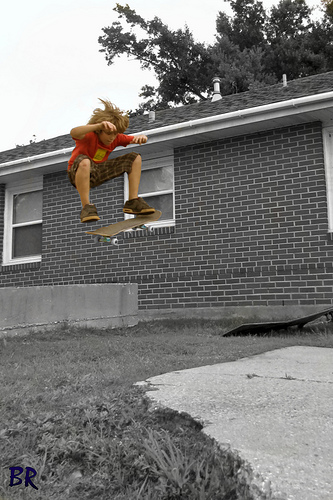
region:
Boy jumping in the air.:
[58, 92, 229, 251]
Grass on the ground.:
[90, 411, 282, 487]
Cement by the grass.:
[99, 328, 329, 477]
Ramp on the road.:
[226, 288, 329, 385]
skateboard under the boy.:
[87, 221, 181, 262]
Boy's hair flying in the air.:
[86, 96, 139, 134]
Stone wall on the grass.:
[27, 264, 158, 335]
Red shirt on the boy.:
[52, 115, 158, 166]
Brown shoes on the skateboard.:
[75, 203, 169, 234]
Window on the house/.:
[5, 182, 87, 282]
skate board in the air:
[80, 206, 174, 239]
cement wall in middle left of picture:
[1, 280, 139, 333]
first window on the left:
[2, 172, 45, 267]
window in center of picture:
[121, 148, 177, 234]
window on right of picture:
[316, 119, 332, 237]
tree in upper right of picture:
[90, 3, 331, 104]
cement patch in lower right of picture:
[136, 343, 331, 496]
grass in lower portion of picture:
[5, 319, 328, 498]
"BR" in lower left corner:
[6, 462, 40, 492]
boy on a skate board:
[60, 96, 155, 222]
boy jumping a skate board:
[62, 102, 162, 213]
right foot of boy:
[77, 199, 98, 217]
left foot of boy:
[118, 197, 153, 212]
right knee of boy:
[72, 151, 90, 166]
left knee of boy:
[121, 150, 140, 166]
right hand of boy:
[96, 118, 112, 129]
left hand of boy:
[132, 131, 142, 140]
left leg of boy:
[98, 149, 150, 211]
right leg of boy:
[62, 151, 99, 218]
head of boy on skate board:
[92, 105, 129, 147]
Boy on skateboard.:
[60, 96, 163, 247]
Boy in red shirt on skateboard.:
[65, 97, 164, 247]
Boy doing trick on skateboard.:
[59, 97, 166, 247]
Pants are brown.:
[70, 150, 141, 188]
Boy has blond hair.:
[66, 96, 163, 220]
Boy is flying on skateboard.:
[68, 95, 162, 245]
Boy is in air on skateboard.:
[70, 97, 163, 243]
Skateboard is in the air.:
[84, 206, 166, 242]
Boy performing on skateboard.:
[60, 96, 164, 243]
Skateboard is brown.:
[88, 208, 173, 242]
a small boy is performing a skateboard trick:
[66, 95, 167, 249]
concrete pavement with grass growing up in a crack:
[266, 351, 332, 485]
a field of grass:
[37, 346, 121, 495]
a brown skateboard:
[84, 205, 162, 246]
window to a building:
[0, 180, 46, 268]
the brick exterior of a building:
[188, 156, 305, 299]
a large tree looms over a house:
[102, 6, 331, 101]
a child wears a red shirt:
[67, 101, 153, 220]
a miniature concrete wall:
[1, 278, 141, 332]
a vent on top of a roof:
[209, 74, 222, 103]